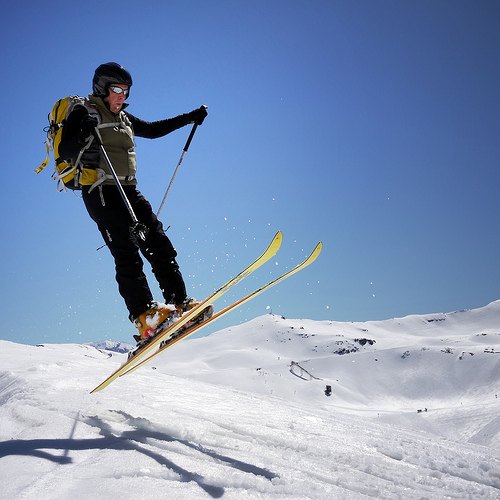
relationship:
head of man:
[94, 62, 133, 113] [46, 61, 213, 334]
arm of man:
[130, 111, 207, 135] [46, 61, 213, 334]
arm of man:
[57, 104, 89, 156] [46, 61, 213, 334]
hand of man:
[189, 106, 208, 126] [46, 61, 213, 334]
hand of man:
[79, 116, 100, 135] [46, 61, 213, 334]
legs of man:
[94, 184, 189, 307] [46, 61, 213, 334]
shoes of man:
[133, 300, 212, 338] [46, 61, 213, 334]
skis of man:
[92, 239, 328, 399] [46, 61, 213, 334]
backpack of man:
[42, 97, 102, 187] [46, 61, 213, 334]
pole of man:
[153, 105, 208, 217] [46, 61, 213, 334]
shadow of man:
[3, 409, 278, 497] [46, 61, 213, 334]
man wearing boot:
[46, 61, 213, 334] [133, 305, 180, 335]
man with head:
[46, 61, 213, 334] [94, 62, 133, 113]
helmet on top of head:
[91, 60, 130, 96] [94, 62, 133, 113]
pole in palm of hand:
[83, 118, 155, 239] [79, 116, 100, 135]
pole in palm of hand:
[150, 112, 208, 215] [189, 106, 208, 126]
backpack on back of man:
[42, 97, 102, 187] [46, 61, 213, 334]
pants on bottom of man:
[88, 184, 189, 309] [46, 61, 213, 334]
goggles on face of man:
[107, 85, 132, 95] [46, 61, 213, 334]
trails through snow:
[70, 386, 494, 498] [7, 308, 498, 499]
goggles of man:
[107, 85, 132, 95] [46, 61, 213, 334]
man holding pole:
[46, 61, 213, 334] [153, 105, 208, 217]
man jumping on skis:
[46, 61, 213, 334] [92, 239, 328, 399]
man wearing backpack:
[46, 61, 213, 334] [42, 97, 102, 187]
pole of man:
[150, 112, 208, 215] [46, 61, 213, 334]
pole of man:
[83, 118, 155, 239] [46, 61, 213, 334]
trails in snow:
[70, 386, 494, 498] [7, 308, 498, 499]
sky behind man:
[2, 3, 497, 330] [46, 61, 213, 334]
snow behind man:
[7, 308, 498, 499] [46, 61, 213, 334]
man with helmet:
[46, 61, 213, 334] [91, 60, 130, 96]